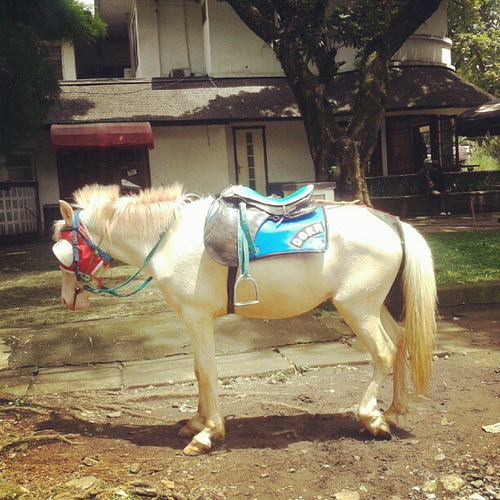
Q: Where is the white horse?
A: On front the house.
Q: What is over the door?
A: An awning.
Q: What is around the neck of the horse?
A: A blue strap.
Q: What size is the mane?
A: Long.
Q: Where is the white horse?
A: In front of a building.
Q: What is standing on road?
A: A white racing horse.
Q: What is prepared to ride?
A: A mule.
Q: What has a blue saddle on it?
A: The white horse.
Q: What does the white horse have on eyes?
A: A red blind.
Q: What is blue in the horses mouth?
A: A blue rein.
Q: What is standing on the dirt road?
A: A white horse.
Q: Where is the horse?
A: On the dirt road.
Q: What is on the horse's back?
A: A blue blanket.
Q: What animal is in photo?
A: Horse.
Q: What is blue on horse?
A: Saddle.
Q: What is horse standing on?
A: Dirt.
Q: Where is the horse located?
A: Road way.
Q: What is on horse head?
A: Red cover.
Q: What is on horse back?
A: Blue saddle.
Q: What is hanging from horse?
A: Blue reins.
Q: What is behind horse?
A: Tree trunk.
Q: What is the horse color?
A: White.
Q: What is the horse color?
A: White.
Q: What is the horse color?
A: White.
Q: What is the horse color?
A: White.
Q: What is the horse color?
A: White.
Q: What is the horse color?
A: White.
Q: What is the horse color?
A: White.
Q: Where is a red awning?
A: Over windows of house in background.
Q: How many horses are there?
A: 1.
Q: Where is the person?
A: Sitting on the bench.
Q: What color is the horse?
A: White.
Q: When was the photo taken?
A: Day time.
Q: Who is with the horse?
A: No one.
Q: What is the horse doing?
A: Looking down.